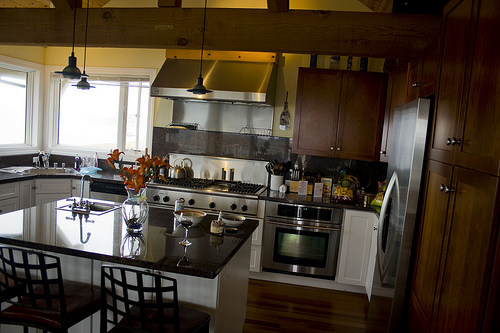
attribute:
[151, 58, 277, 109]
vent hood — stainless steel, silver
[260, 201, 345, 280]
oven — stainless steel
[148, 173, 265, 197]
stove top — stainless steel, six burners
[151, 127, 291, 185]
backsplash — black, stainless steel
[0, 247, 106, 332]
chair — a bar stool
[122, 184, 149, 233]
vase — glass, clear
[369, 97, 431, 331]
refrigerator — built into wall, stainless steel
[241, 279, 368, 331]
floor — brown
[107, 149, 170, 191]
flowers — orange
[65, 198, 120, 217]
sink — metal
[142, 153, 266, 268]
stove — gas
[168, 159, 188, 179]
teapot — stainless steel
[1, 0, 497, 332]
kitchen — large